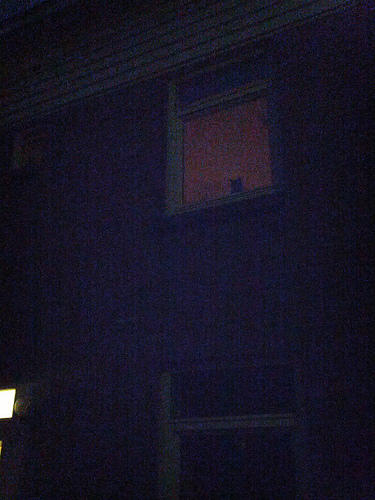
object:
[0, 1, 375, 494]
building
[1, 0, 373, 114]
roof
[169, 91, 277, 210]
window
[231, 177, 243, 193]
cat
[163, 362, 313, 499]
door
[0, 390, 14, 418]
light